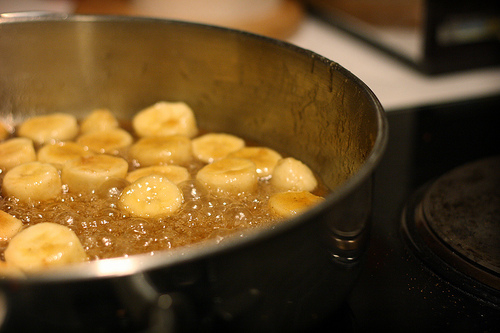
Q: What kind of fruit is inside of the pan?
A: Sliced bananas.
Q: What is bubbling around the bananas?
A: Hot liquid.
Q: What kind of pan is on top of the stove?
A: A saute pan.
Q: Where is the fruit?
A: In the pan.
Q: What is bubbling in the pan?
A: Butter.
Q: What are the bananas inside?
A: Silver pot.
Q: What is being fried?
A: Bananas.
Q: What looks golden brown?
A: Bananas.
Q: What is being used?
A: A pot.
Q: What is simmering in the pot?
A: Banana's.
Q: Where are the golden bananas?
A: In the pot.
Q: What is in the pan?
A: Bananas.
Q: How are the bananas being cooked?
A: Fried.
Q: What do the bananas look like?
A: Brown.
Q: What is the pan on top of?
A: Stove.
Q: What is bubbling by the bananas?
A: Oil.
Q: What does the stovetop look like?
A: Black.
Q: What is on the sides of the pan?
A: Oil.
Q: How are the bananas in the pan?
A: Laying.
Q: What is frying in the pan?
A: Banana pieces.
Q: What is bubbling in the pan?
A: Bananas in butter.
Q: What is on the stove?
A: A skillet.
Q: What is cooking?
A: Bananas.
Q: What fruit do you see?
A: Bananas.